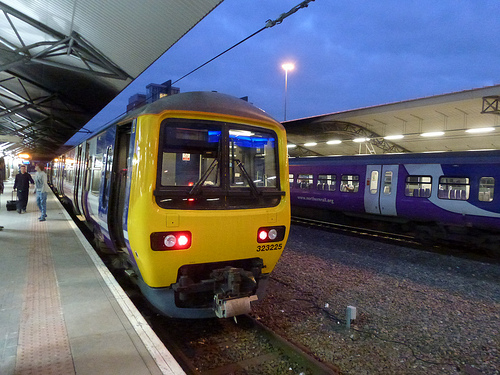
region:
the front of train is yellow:
[139, 114, 298, 289]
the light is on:
[153, 228, 198, 260]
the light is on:
[253, 222, 284, 247]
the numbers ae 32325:
[247, 240, 287, 255]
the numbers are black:
[251, 240, 286, 255]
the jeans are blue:
[33, 193, 47, 218]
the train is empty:
[301, 150, 498, 211]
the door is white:
[365, 165, 396, 218]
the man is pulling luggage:
[6, 169, 39, 213]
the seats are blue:
[412, 183, 436, 195]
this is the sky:
[326, 18, 451, 70]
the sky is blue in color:
[353, 10, 478, 86]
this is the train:
[146, 103, 281, 336]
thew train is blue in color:
[341, 191, 438, 227]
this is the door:
[361, 167, 393, 227]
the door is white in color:
[368, 177, 391, 203]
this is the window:
[397, 172, 429, 191]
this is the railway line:
[186, 342, 293, 371]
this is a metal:
[267, 320, 302, 368]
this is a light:
[277, 58, 302, 83]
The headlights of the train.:
[151, 216, 296, 250]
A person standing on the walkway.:
[26, 158, 44, 228]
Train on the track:
[124, 76, 309, 330]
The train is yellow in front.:
[138, 107, 296, 294]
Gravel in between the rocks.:
[300, 245, 417, 348]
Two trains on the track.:
[88, 79, 499, 241]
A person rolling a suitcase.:
[12, 153, 34, 215]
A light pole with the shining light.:
[247, 36, 304, 125]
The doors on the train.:
[341, 150, 411, 222]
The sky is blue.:
[219, 7, 431, 104]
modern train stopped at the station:
[35, 82, 298, 331]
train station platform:
[2, 165, 189, 370]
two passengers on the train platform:
[8, 158, 53, 224]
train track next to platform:
[153, 310, 348, 373]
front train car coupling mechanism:
[178, 256, 265, 321]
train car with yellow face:
[87, 83, 289, 328]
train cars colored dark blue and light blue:
[288, 145, 498, 234]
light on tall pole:
[278, 58, 299, 118]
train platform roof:
[0, 0, 223, 160]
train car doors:
[362, 165, 400, 219]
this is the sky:
[335, 35, 474, 97]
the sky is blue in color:
[321, 3, 408, 83]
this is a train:
[118, 88, 250, 290]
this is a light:
[253, 222, 276, 237]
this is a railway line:
[176, 340, 296, 372]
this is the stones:
[393, 304, 430, 331]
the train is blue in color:
[381, 177, 436, 217]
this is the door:
[113, 132, 132, 219]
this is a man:
[36, 145, 47, 212]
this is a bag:
[4, 195, 16, 215]